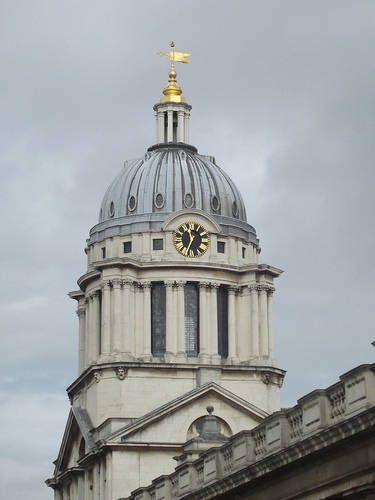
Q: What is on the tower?
A: Clock.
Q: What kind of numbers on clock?
A: Roman Numerals.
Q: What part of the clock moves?
A: Hands.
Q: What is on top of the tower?
A: Weather Vane.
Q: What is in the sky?
A: Clouds.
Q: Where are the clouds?
A: In sky.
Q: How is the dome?
A: Tan.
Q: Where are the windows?
A: Under clock.